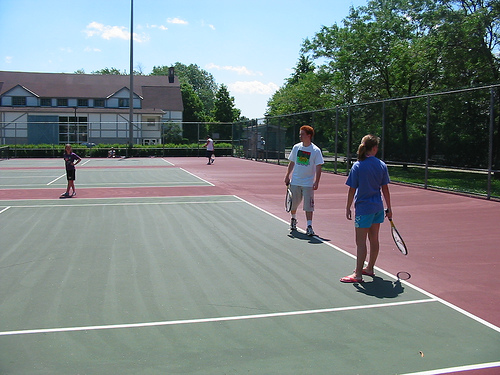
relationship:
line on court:
[0, 295, 441, 339] [0, 150, 499, 373]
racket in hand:
[383, 209, 409, 256] [383, 210, 393, 220]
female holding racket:
[338, 131, 396, 285] [383, 209, 408, 257]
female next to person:
[338, 131, 396, 285] [281, 125, 326, 237]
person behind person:
[201, 132, 218, 164] [57, 139, 84, 199]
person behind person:
[201, 132, 218, 164] [281, 125, 326, 237]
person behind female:
[201, 132, 218, 164] [338, 131, 396, 285]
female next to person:
[338, 131, 396, 285] [285, 125, 323, 238]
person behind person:
[201, 134, 216, 165] [59, 143, 81, 198]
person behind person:
[201, 134, 216, 165] [285, 125, 323, 238]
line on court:
[0, 295, 441, 339] [5, 157, 490, 374]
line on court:
[167, 162, 224, 191] [4, 163, 218, 200]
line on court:
[385, 335, 498, 374] [6, 192, 496, 373]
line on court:
[7, 191, 264, 213] [6, 192, 496, 373]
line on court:
[214, 183, 496, 355] [6, 192, 496, 373]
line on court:
[0, 287, 450, 347] [6, 192, 496, 373]